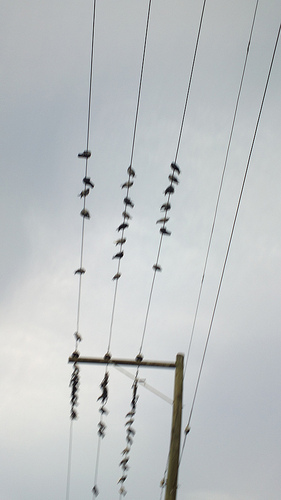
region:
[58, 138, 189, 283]
black birds sitting on black power lines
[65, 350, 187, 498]
brown wooden electric line support pole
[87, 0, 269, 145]
black power lines in sky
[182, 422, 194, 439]
black object on surface of black power line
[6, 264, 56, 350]
white misty cloud in grey sky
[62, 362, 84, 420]
line of birds sitting close to each other on power line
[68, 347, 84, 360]
black round connectors between power line and wooden support pole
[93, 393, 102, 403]
tail of black bird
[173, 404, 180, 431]
striation mark on brown wooden pole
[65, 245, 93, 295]
one black bird on black power line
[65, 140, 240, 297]
Group of birds together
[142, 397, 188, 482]
Pole is made of wood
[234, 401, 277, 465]
The sky is full of clouds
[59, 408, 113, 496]
Power lines on the pole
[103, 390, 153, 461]
The birds are grouped together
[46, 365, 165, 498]
Birds are all sitting together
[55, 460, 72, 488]
the power line is straight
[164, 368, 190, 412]
The wood has splinters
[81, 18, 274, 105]
Several power lines are perpendicular to each other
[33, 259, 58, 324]
Sky has clouds in it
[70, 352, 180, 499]
An electrical post near the birds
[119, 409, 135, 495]
Birds on the wire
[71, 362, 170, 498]
Wires connected to the post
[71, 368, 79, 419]
The birds are black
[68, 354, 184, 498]
The post is made of wood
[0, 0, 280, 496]
The sky above the birds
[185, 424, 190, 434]
A lone bird on the wire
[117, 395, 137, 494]
The birds are in a group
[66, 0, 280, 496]
The black wire is below the sky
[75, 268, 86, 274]
The bird is above the ground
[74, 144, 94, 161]
little black bird on a wire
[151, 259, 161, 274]
little black bird on a wire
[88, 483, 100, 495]
little black bird on a wire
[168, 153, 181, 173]
little black bird on a wire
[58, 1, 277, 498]
thin black utility wires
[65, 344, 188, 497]
brown wooden utility pole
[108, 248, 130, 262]
little black bird on a wire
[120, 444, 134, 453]
little black bird on a wire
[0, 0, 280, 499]
overcast grey sky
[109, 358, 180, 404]
triangle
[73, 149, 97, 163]
bird on a wire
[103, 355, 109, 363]
bird on a wire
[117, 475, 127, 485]
bird on a wire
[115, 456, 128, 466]
bird on a wire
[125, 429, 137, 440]
bird on a wire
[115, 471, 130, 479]
bird on a wire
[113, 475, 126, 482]
bird on a wire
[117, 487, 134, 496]
bird on a wire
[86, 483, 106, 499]
bird on a wire